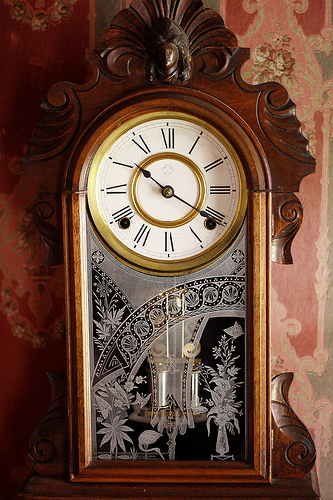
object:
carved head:
[146, 15, 190, 81]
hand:
[171, 194, 216, 223]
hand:
[133, 162, 162, 189]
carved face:
[159, 39, 180, 69]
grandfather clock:
[19, 0, 321, 499]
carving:
[20, 79, 75, 171]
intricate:
[272, 366, 322, 471]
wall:
[11, 8, 326, 484]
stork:
[138, 430, 164, 459]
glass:
[86, 247, 249, 461]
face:
[85, 118, 241, 278]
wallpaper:
[240, 19, 329, 77]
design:
[97, 252, 238, 456]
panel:
[82, 218, 248, 462]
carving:
[93, 0, 239, 86]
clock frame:
[250, 171, 273, 478]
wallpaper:
[283, 296, 331, 351]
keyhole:
[205, 216, 217, 230]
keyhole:
[119, 216, 130, 229]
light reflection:
[163, 50, 174, 65]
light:
[259, 216, 269, 384]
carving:
[271, 367, 302, 474]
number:
[160, 122, 177, 149]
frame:
[65, 156, 91, 335]